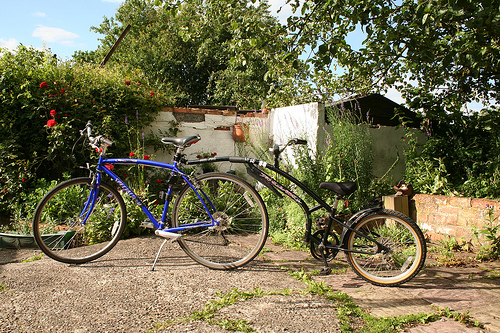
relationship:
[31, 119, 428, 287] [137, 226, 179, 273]
bicycle has kick stand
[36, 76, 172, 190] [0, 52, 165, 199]
flowers on bush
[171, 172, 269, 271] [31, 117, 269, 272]
wheel of bike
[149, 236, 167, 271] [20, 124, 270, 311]
kick stand on bike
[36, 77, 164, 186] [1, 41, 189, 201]
flowers on bushes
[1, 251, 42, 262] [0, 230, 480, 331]
grass growing in cracks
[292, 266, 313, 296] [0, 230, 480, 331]
grass growing in cracks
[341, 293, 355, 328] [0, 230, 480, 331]
grass growing in cracks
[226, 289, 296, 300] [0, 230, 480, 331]
grass growing in cracks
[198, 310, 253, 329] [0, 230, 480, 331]
grass growing in cracks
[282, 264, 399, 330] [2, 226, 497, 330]
grass growing in cement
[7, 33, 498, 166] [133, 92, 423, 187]
trees surrounding building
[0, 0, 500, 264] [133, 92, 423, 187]
foliage surrounding building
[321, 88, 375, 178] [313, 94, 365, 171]
flowers on bushes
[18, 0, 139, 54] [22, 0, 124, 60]
sky with clouds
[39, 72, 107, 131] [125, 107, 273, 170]
roses climbing over wall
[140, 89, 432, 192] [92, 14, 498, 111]
house under trees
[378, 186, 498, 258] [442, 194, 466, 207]
wall made of bricks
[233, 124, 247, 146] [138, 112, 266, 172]
pot on wall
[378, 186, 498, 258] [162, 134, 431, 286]
wall near bike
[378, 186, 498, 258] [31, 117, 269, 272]
wall near bike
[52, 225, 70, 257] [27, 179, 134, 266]
spokes in tire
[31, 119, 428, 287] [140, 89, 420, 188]
bicycle in front house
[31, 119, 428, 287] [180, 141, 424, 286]
bicycle with seat extension